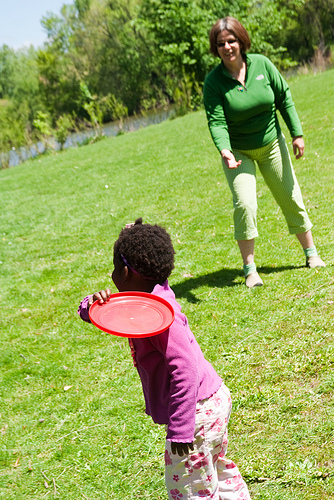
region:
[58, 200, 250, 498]
Small child holding frisbee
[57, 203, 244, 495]
Small child playing outside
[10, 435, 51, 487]
Small patch of green grass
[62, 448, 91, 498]
Small patch of green grass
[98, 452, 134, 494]
Small patch of green grass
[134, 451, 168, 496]
Small patch of green grass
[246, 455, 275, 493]
Small patch of green grass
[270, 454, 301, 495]
Small patch of green grass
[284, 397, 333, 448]
Small patch of green grass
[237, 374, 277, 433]
Small patch of green grass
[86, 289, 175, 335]
a red frisbee in a girl's hand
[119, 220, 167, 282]
a purple headband in a girl's hair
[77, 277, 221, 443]
a purple shirt on a girl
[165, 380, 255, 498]
white pants with purple flowers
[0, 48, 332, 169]
water behind a woman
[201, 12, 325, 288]
a woman with brown hair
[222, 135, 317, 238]
light green capris on a woman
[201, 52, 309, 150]
a dark green shirt on a woman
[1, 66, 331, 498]
a green grassy field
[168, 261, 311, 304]
the shadow of a woman on the grass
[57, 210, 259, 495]
Small child standing outside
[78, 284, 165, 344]
Bright red frisbee on hand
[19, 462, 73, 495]
Patch of green grass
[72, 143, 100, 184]
Patch of green grass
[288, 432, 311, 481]
Patch of green grass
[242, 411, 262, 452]
Patch of green grass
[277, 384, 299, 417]
Patch of green grass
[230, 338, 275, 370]
Patch of green grass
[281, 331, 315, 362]
Patch of green grass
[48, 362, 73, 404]
Patch of green grass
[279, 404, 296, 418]
part of a field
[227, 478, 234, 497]
part of a trouser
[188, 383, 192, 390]
part of a sweater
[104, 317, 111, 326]
part of a floater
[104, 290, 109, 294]
part of a finger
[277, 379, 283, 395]
part of a garden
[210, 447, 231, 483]
part of a trouser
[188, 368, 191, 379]
part of an elbow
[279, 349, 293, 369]
part of a garden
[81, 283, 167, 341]
The frisbee is red.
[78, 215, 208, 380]
The little girl is holding frisbee in hand.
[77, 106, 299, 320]
People are playing frisbee in the grass.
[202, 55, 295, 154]
The lady is wearing a green sweater.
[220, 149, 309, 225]
The woman is wearing green capris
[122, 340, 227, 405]
The little girl is wearing a pink sweater.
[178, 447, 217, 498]
Pink flowers on the pants.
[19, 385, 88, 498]
Branches and leaves on the grass.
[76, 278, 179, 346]
The girl is getting ready to throw frisbee.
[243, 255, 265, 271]
The woman is wearing green socks.